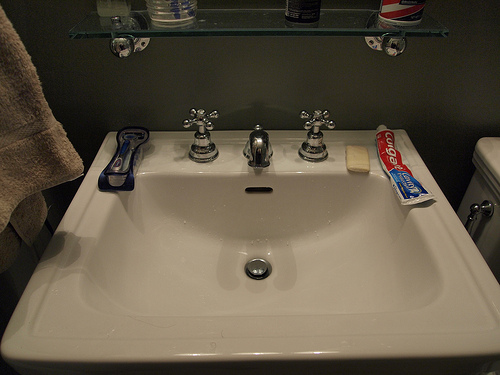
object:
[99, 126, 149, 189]
razor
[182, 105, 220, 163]
knobs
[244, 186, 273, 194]
hole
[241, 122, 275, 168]
fixture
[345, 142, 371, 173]
soap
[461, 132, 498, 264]
toilet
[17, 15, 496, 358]
bathroom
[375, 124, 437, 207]
hygiene items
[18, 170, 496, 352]
sink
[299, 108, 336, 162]
knob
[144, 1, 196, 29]
glass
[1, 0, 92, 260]
towel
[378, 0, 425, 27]
can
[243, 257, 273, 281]
drain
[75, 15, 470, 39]
glass shelf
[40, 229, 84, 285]
shadow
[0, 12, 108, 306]
wall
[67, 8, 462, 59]
shelf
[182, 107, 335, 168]
faucet